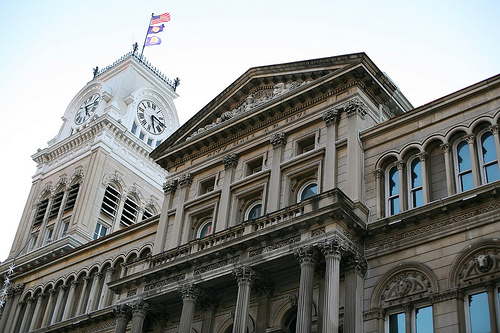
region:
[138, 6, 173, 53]
america's flag on top of a building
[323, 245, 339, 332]
a pillar of a building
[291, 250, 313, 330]
a pillar of a building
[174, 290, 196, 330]
a pillar of a building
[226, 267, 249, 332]
a pillar of a building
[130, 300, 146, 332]
a pillar of a building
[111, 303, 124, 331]
a pillar of a building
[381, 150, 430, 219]
a window on a building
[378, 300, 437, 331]
a window on a building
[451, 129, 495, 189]
a window on a building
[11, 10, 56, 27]
section of clear blue skies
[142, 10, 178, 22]
American flag flying in the wind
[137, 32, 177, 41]
blue flag with white circle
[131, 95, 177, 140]
large clock in building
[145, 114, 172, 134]
hour hand on clock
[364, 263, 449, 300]
decorative pattern on building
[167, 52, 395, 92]
raised edge of building roof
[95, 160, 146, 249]
white window in white building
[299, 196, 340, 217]
rust on old building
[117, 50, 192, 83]
raised edge of white building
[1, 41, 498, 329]
Old building on a street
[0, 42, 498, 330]
Building is made of stone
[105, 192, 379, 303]
Building has a balcony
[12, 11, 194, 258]
A tower next to building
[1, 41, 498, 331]
Building is tan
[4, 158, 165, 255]
Inferior part of tower is tan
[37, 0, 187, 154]
Top of tower is white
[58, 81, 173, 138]
Towers has two clocks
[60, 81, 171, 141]
Clocks a white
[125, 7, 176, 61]
Clocks have roman numerals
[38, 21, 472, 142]
The sky is hazy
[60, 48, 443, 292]
There are 2 buildings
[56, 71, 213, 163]
There are 2 clocks shown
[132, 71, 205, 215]
The clock shows 5:15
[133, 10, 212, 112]
There are 3 flags on top of the building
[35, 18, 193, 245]
This building is white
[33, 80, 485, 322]
This building is tan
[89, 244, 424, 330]
This building has 6 columns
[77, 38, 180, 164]
This building has iron at the top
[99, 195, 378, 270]
This building has a guard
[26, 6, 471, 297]
stately stone building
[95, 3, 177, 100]
American flag flying in the wind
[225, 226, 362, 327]
stone pillars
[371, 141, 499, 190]
arched window design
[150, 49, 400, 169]
Roman style facade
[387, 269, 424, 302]
horse head gargoyles on side of building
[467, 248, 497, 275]
bull head gargoyle on side of building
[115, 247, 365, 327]
building support columns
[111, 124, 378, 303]
stone balcony on government building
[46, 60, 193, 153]
Roman numeral clock tower